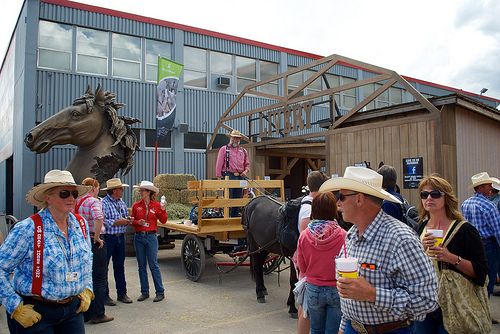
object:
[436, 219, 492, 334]
bag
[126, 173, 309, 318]
horsecart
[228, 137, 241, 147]
gray hair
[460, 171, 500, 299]
man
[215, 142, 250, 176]
shirt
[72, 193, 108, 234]
shirt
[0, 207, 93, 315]
shirt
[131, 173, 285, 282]
cart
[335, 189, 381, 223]
head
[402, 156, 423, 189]
sign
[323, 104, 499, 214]
wall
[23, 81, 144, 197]
statue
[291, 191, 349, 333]
girl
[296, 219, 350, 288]
hoodie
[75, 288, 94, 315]
glove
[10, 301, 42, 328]
glove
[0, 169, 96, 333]
man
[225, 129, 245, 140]
hat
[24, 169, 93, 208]
hat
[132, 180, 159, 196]
hat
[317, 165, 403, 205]
hat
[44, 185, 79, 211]
head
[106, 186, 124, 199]
head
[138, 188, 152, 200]
head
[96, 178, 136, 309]
man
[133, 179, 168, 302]
man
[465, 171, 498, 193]
hat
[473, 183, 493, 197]
head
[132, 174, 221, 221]
hay bale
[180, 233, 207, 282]
wheel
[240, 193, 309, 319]
horse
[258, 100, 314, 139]
livery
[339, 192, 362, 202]
sunglasses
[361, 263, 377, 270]
object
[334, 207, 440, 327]
shirt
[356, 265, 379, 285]
pocket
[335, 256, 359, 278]
cup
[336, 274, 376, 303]
hand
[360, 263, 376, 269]
cellphone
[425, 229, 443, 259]
glass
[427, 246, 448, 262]
hand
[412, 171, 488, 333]
woman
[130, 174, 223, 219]
hay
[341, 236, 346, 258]
straw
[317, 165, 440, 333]
man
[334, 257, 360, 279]
drink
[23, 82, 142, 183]
head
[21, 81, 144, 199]
horse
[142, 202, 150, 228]
suspenders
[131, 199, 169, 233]
shirt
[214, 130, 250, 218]
man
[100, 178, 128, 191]
hat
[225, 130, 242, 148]
man's head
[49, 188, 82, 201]
sunglasses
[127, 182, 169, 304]
woman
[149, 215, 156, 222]
red